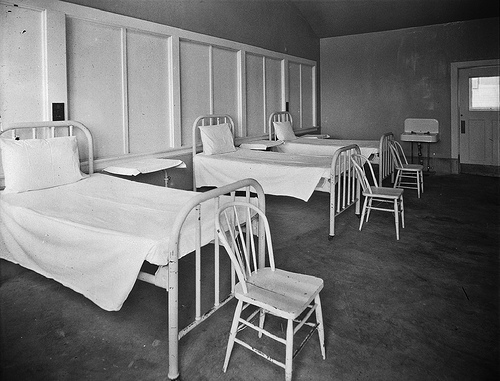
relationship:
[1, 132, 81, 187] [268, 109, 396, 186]
pillow on bed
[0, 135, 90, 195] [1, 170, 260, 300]
pillow on bed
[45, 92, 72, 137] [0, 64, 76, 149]
outlet on wall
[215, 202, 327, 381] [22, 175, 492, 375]
chair on floor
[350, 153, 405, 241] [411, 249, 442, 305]
chair on floor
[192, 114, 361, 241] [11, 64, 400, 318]
bed are in room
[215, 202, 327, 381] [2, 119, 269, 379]
chair next to bed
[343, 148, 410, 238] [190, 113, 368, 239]
chair next to bed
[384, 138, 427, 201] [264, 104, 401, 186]
chair next to bed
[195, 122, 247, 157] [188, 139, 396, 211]
pillow on bed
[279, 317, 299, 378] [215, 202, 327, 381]
leg on chair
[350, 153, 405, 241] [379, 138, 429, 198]
chair beside chair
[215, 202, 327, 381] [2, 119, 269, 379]
chair at end of bed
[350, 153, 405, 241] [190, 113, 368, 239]
chair at end of bed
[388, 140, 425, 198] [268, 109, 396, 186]
chair at end of bed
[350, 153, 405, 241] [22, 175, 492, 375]
chair on floor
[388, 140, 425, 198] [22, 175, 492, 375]
chair on floor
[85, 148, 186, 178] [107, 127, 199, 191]
cloth on table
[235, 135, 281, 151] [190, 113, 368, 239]
cloth beside bed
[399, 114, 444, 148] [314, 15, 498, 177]
sink on wall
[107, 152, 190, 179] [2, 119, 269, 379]
table beside bed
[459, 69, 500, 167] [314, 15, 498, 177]
white door on wall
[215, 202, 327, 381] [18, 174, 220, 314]
chair in front of bed